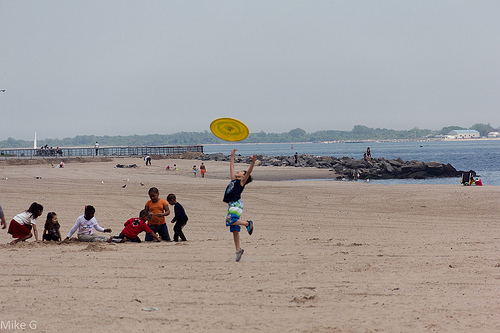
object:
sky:
[1, 2, 497, 140]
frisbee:
[210, 118, 251, 142]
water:
[0, 142, 500, 186]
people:
[1, 184, 187, 243]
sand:
[1, 153, 499, 330]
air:
[0, 0, 500, 137]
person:
[219, 148, 260, 260]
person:
[365, 145, 373, 158]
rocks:
[339, 158, 375, 179]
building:
[444, 128, 483, 140]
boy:
[106, 210, 162, 243]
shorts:
[224, 201, 246, 234]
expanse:
[0, 155, 474, 177]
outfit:
[66, 213, 104, 240]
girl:
[362, 152, 373, 166]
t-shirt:
[144, 198, 168, 227]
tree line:
[1, 125, 496, 147]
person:
[7, 200, 45, 245]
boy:
[218, 147, 261, 262]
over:
[164, 192, 190, 241]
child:
[59, 205, 115, 242]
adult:
[144, 156, 152, 166]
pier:
[1, 145, 203, 155]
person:
[165, 194, 190, 242]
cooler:
[474, 178, 483, 187]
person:
[461, 170, 477, 187]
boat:
[32, 129, 39, 151]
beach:
[0, 157, 500, 333]